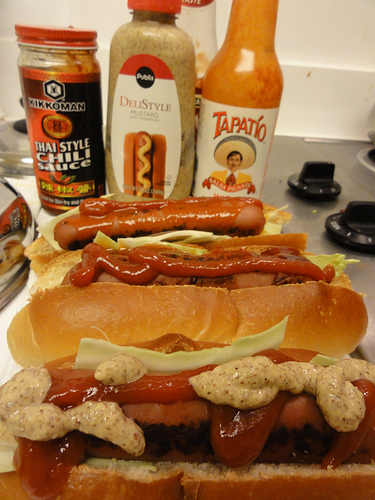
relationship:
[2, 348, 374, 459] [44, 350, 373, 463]
mustard on hot dog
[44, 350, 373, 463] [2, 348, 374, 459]
hot dog on mustard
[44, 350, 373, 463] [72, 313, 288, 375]
hot dog next to cheese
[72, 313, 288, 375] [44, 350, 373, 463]
cheese next to hot dog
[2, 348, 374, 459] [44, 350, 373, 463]
mustard next to hot dog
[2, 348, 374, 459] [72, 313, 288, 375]
mustard next to cheese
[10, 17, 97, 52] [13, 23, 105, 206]
lid on chili sauce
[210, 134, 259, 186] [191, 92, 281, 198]
man on label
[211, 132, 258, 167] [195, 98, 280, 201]
sombrero on label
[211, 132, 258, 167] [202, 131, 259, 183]
sombrero on man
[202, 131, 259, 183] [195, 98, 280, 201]
man on label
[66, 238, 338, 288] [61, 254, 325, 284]
ketchup on a dogs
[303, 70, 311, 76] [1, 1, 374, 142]
speck on wall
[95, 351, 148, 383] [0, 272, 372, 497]
mustard on a hot dog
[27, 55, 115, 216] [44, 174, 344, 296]
ketchup covered hot dog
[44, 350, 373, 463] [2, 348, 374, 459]
hot dog with mustard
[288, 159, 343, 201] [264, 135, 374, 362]
dial on oven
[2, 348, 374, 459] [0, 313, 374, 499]
mustard on hot dog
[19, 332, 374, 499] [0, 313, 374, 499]
bun on hot dog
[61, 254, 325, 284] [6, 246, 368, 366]
dogs on bun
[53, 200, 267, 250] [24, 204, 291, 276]
dogs on bun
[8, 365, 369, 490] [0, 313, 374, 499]
ketchup on hot dog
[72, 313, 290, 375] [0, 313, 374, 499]
cabbage on hot dog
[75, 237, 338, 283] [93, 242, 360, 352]
ketchup on hotdog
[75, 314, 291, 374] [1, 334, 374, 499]
cabbage on hotdog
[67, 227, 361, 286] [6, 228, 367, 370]
toppings on hot dog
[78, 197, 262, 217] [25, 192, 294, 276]
toppings on hot dog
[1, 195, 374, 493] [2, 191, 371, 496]
toppings on dogs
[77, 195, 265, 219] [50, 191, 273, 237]
ketchup on hot dogs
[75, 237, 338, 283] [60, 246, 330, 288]
ketchup on hot dogs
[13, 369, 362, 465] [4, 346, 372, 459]
ketchup on hot dogs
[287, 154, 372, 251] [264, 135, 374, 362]
dials on oven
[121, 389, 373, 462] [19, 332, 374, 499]
hot dog on bun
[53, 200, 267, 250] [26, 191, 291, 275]
dogs on bun